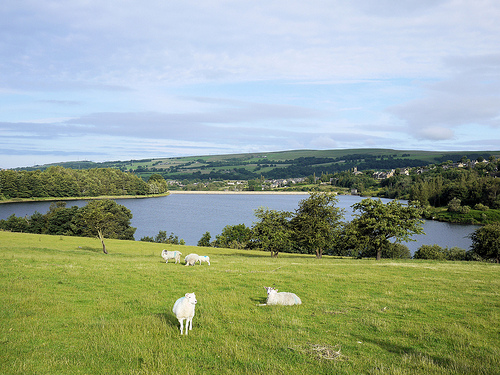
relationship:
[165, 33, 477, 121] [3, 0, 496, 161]
clouds in sky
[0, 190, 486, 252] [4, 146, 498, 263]
lake in background